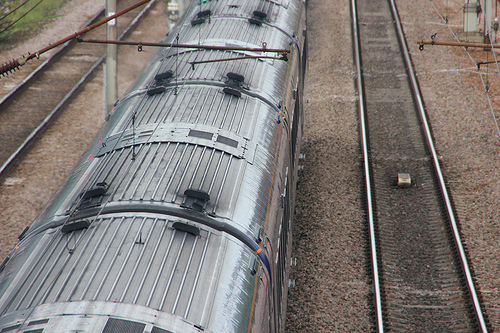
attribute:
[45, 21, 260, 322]
train — gray, silver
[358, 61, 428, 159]
tracks — silver, empty, parallel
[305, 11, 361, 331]
gravel — brown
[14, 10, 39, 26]
grass — green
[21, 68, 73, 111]
tracks — gray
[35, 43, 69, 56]
power line — brown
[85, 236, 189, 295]
roof — shiny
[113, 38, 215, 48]
bar — rusty